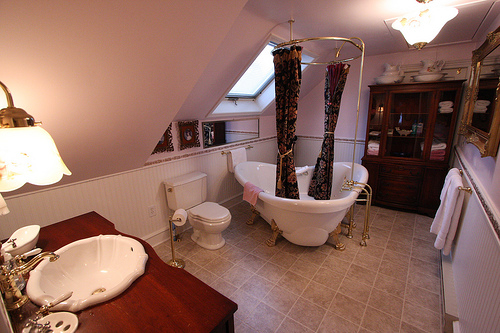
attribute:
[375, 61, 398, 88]
bowl — pitcher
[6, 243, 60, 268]
faucet — gold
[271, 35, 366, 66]
rod — for shower,  gold ,   circle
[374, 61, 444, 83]
basins —  two, for wash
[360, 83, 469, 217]
hutch —  china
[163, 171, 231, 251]
toilet —  white,  porcelain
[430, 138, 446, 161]
towels —  extra 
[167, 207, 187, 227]
holder —  brass, for toilet paper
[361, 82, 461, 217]
cabinet —  free standing,  dark wood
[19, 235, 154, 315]
sink — decorated, white, of vanity , with wood top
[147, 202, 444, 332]
floor — tiled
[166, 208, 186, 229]
paper — rolled, for toilet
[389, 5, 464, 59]
bulb — large, hanging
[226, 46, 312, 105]
light — large,  sky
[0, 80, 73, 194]
lamp — tulip,  glass,  on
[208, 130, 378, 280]
bathtub — large, shaped, decorated,  white,  with claw foot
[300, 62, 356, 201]
curtain — hanging,  tied,  for shower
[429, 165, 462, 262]
toowel — white, hanging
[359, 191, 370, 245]
pipe — gold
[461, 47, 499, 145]
mirror — long, large,  framed 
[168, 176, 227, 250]
toilet — white